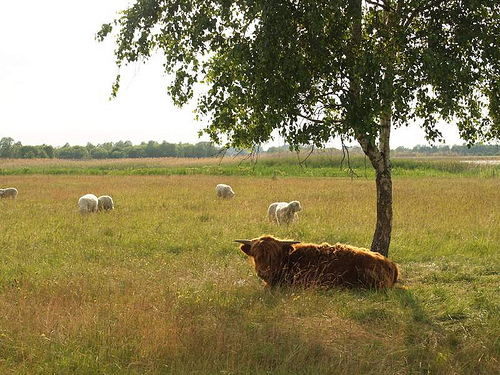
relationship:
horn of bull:
[234, 236, 251, 249] [239, 237, 399, 291]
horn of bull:
[278, 239, 299, 246] [239, 237, 399, 291]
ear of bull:
[282, 245, 296, 252] [239, 237, 399, 291]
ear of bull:
[240, 244, 259, 254] [239, 237, 399, 291]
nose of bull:
[258, 265, 269, 279] [239, 237, 399, 291]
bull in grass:
[239, 237, 399, 291] [241, 285, 392, 330]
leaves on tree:
[90, 1, 500, 149] [95, 1, 498, 289]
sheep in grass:
[267, 201, 302, 225] [241, 285, 392, 330]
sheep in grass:
[214, 185, 238, 200] [241, 285, 392, 330]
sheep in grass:
[77, 194, 114, 211] [241, 285, 392, 330]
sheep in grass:
[0, 186, 18, 201] [241, 285, 392, 330]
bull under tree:
[239, 237, 399, 291] [95, 1, 498, 289]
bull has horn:
[239, 237, 399, 291] [234, 236, 251, 249]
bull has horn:
[239, 237, 399, 291] [278, 239, 299, 246]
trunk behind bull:
[347, 12, 391, 253] [239, 237, 399, 291]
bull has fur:
[239, 237, 399, 291] [248, 241, 283, 256]